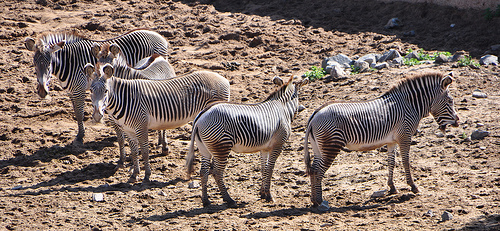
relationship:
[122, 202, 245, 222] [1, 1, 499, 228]
shadow on ground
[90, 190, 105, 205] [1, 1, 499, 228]
paper on ground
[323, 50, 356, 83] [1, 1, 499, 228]
rock on ground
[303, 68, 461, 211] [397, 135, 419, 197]
zebra has a leg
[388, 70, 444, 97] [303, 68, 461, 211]
mane on zebra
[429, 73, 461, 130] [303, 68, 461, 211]
head of zebra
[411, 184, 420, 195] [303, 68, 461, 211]
hoof on zebra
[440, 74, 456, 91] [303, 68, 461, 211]
ear on zebra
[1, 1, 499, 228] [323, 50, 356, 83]
ground with rock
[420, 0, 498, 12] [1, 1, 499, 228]
wall by ground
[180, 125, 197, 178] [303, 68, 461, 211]
tail on zebra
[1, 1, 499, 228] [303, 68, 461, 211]
ground with zebra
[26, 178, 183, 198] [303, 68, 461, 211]
shadow of zebra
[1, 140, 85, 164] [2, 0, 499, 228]
shadow on sand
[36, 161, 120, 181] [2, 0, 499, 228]
shadow on sand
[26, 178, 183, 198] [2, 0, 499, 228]
shadow on sand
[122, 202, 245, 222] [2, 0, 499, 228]
shadow on sand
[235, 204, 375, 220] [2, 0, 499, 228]
shadow on sand